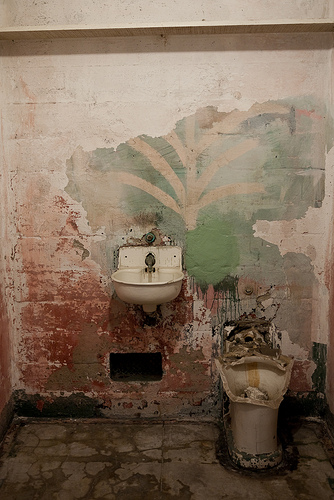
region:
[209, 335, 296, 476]
a broken white toilet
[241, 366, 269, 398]
a stain on the inside of a toilet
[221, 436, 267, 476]
a bunch of dirt on a toilet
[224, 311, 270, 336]
a bunch of grime on the wall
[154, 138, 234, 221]
a tree painted on the wall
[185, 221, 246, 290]
a spot of green paint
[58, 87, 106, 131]
a bunch of white bricks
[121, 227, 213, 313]
a white sink on the wall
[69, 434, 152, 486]
a dirty bathroom floor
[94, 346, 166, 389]
a hole in the wall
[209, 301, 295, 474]
a toilet has been smashed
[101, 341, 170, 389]
a hole in a bathroom wall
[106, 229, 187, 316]
a small basin in a derelict bathroom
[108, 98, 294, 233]
painting of a plant on a bathroom wall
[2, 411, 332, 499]
stained concrete floor of a bathroom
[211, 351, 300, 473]
base of a broken toilet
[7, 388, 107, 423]
dark moldy patch on a wall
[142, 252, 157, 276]
rusty old faucet in a basin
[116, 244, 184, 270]
splashback on an old basin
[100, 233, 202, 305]
sink on a wall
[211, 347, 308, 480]
busted toilet on the ground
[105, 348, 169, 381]
hole in a wall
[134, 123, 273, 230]
chipped paint on wall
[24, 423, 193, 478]
cracked concrete on floor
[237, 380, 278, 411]
broken edge of toilet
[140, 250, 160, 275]
faucet of a sink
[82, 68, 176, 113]
white paint on a wall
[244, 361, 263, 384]
rust on a toilet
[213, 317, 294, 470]
destroyed and dirty white porcelain toilet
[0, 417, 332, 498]
cracked and dirty cement floor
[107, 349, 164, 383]
square hole cut in the brick wall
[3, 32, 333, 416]
dilapidated peeling brick wall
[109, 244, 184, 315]
old fashioned white colored metal sink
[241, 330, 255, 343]
pipe for toilet water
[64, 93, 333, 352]
section of the wall that has part of a mural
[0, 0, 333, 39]
upper wall lip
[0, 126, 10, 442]
brick side wall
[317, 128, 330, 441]
brick side wall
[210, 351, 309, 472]
Broken white urinal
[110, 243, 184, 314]
Dirty white bathroom sink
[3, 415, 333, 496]
Cracked and stained concrete floor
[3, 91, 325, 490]
Old bathroom with sink and toliet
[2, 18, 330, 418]
Red and white wall with rectangular hole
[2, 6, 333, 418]
Red, white and green brick wall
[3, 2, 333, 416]
Brick wall with ruined tree design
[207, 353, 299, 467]
Toliet bowl missing seat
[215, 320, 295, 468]
Toliet bowl with missing tank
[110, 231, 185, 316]
White sink with pipe above it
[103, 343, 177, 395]
dark hole in bathroom wall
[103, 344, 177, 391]
dark hole in bathroom wall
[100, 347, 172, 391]
dark hole in bathroom wall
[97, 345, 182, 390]
dark hole in bathroom wall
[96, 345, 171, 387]
dark hole in bathroom wall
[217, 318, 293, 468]
broken white toilet bowl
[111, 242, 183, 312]
white bathroom sink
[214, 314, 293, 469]
toilet without a tank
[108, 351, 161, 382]
dark rectangular hole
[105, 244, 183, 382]
hole under a sink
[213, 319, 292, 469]
toilet with no seat or lid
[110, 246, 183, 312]
dirty bathroom sink